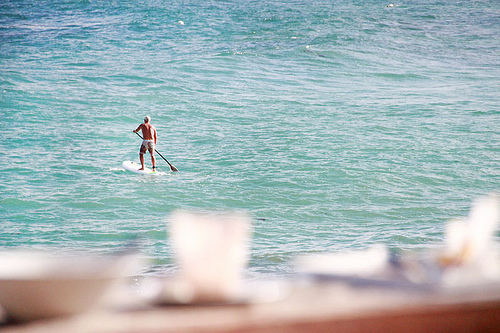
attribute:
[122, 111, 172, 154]
man — holding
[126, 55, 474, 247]
water — light blue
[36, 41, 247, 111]
waves — small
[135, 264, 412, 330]
table — brown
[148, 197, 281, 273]
cup — white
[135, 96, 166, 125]
hat — white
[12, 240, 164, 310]
bowl — white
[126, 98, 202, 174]
man — rowing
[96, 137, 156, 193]
surfboard — white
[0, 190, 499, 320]
objects — blurry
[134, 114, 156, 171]
man — shirtless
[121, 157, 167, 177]
paddle board — white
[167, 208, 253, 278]
cup — blurry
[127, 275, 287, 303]
saucer — blurry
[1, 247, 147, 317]
bowl — blurry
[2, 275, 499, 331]
ledge — blurry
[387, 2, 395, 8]
ball — white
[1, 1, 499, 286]
water — Bluish-green, ocean, rough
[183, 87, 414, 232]
water — blue